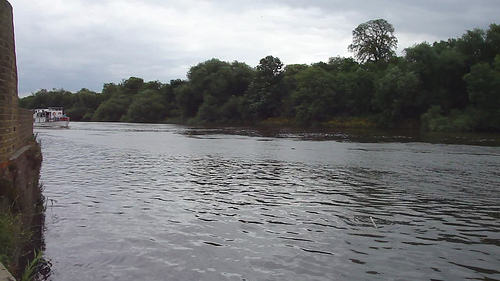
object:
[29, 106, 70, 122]
building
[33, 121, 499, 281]
river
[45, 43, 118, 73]
cloud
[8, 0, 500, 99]
sky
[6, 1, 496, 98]
clouds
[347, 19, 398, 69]
green tree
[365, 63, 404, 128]
trees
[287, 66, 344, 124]
trees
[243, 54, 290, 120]
trees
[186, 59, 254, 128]
trees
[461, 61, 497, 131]
trees